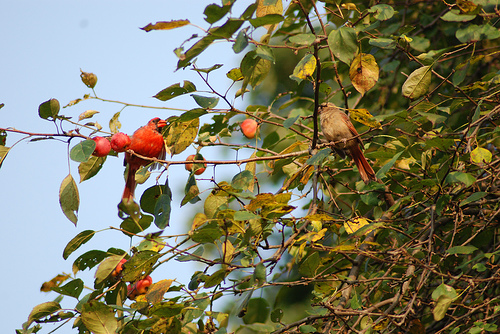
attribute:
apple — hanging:
[239, 117, 258, 139]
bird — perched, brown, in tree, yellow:
[315, 102, 379, 186]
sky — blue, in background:
[2, 2, 323, 333]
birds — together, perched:
[123, 101, 379, 206]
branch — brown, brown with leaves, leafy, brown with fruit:
[2, 124, 368, 167]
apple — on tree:
[91, 136, 112, 158]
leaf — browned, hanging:
[350, 50, 380, 96]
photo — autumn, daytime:
[0, 0, 500, 334]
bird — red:
[118, 115, 168, 201]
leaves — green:
[2, 0, 497, 331]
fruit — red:
[111, 131, 131, 153]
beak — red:
[157, 119, 167, 127]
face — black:
[150, 116, 162, 131]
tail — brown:
[347, 144, 376, 182]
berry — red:
[136, 280, 149, 293]